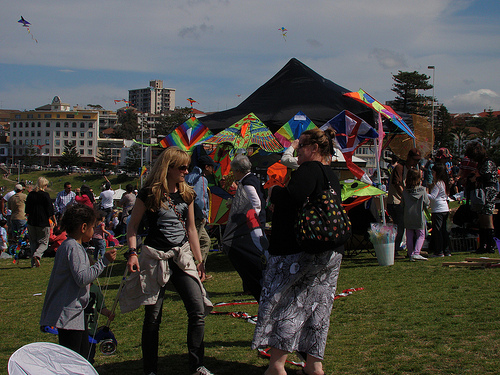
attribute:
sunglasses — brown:
[177, 165, 190, 172]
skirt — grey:
[248, 245, 345, 359]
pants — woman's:
[134, 247, 219, 373]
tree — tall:
[386, 69, 431, 155]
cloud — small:
[444, 84, 500, 111]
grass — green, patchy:
[2, 163, 499, 372]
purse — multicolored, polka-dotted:
[294, 187, 356, 249]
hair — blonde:
[143, 148, 197, 208]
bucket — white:
[365, 218, 401, 266]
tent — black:
[179, 57, 401, 131]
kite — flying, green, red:
[15, 13, 46, 45]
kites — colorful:
[15, 8, 294, 114]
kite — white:
[6, 340, 102, 374]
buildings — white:
[9, 77, 182, 168]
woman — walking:
[123, 145, 216, 374]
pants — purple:
[405, 218, 427, 261]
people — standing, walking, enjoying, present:
[2, 124, 500, 373]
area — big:
[1, 1, 499, 374]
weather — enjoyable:
[0, 0, 496, 119]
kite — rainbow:
[276, 25, 291, 40]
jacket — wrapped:
[115, 238, 217, 315]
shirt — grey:
[38, 238, 105, 331]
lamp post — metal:
[426, 65, 437, 158]